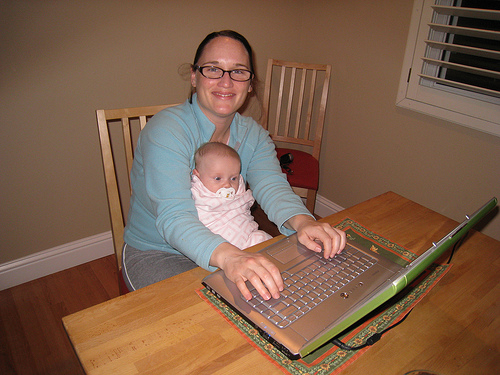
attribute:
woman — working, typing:
[111, 22, 344, 298]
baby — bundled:
[173, 141, 272, 260]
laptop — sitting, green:
[195, 187, 500, 359]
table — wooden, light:
[60, 185, 500, 374]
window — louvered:
[384, 0, 500, 148]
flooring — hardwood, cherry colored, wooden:
[4, 185, 341, 374]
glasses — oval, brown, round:
[191, 62, 259, 84]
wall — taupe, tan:
[1, 0, 499, 273]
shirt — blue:
[119, 93, 327, 263]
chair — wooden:
[85, 101, 187, 292]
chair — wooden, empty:
[245, 55, 339, 225]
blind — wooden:
[413, 72, 499, 109]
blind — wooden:
[418, 55, 500, 82]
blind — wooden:
[421, 32, 500, 62]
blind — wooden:
[424, 18, 499, 42]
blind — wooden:
[431, 1, 500, 18]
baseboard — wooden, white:
[0, 220, 128, 310]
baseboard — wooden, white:
[309, 189, 350, 229]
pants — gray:
[112, 234, 210, 300]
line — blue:
[118, 238, 141, 302]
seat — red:
[253, 144, 326, 192]